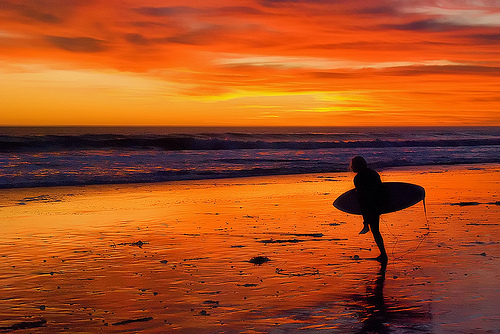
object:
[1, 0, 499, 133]
sky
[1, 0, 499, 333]
picture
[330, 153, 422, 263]
person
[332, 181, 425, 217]
surfboard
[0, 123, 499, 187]
water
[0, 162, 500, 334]
sand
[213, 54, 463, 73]
cloud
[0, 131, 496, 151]
wave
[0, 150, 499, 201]
coastline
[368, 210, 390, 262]
leg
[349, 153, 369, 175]
hair